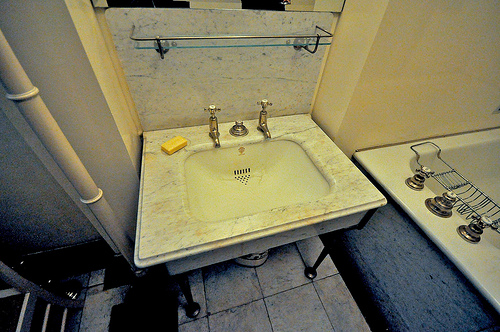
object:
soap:
[161, 136, 188, 155]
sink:
[134, 114, 387, 268]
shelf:
[130, 25, 334, 59]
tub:
[350, 127, 499, 312]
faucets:
[405, 165, 435, 190]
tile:
[264, 282, 337, 331]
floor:
[237, 301, 320, 330]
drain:
[233, 168, 251, 186]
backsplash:
[103, 7, 334, 131]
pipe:
[0, 37, 130, 255]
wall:
[1, 1, 64, 31]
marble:
[400, 271, 446, 319]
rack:
[408, 140, 500, 232]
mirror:
[98, 0, 344, 14]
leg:
[305, 232, 345, 280]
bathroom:
[2, 1, 496, 330]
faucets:
[204, 105, 221, 148]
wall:
[389, 33, 457, 125]